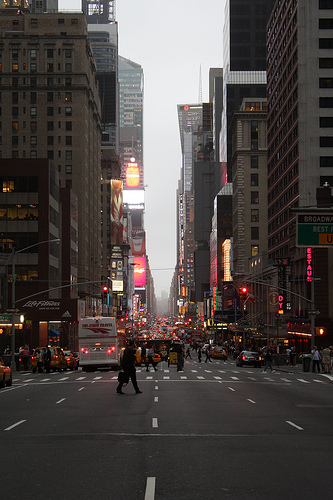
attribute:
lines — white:
[2, 358, 332, 499]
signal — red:
[241, 287, 246, 291]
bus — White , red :
[77, 310, 126, 370]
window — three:
[244, 99, 263, 116]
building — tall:
[0, 5, 102, 318]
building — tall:
[0, 157, 63, 354]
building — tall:
[59, 187, 79, 353]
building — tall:
[118, 51, 144, 228]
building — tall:
[263, 0, 331, 365]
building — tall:
[231, 97, 264, 349]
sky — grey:
[58, 0, 223, 296]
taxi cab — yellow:
[127, 342, 164, 369]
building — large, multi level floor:
[32, 191, 61, 267]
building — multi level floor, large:
[78, 203, 101, 272]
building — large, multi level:
[267, 191, 299, 242]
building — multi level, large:
[204, 208, 222, 275]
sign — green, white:
[285, 193, 329, 254]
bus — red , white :
[77, 316, 118, 372]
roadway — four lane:
[5, 327, 331, 495]